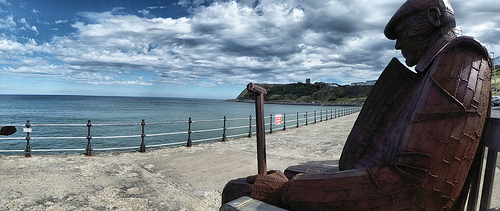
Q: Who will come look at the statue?
A: Tourists.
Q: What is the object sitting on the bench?
A: A statue.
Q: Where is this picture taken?
A: In front of an ocean.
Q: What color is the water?
A: Blue.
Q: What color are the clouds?
A: White.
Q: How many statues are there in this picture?
A: One.